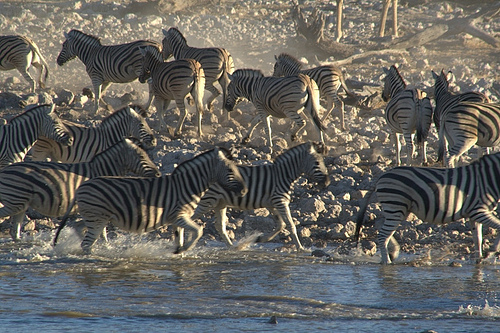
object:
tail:
[352, 185, 375, 243]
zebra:
[353, 152, 500, 262]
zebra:
[225, 68, 326, 148]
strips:
[102, 186, 169, 217]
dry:
[430, 127, 438, 141]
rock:
[301, 196, 328, 212]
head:
[297, 139, 329, 188]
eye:
[312, 161, 320, 165]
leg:
[272, 205, 304, 251]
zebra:
[192, 140, 332, 250]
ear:
[212, 144, 220, 155]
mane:
[171, 149, 214, 175]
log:
[294, 20, 442, 65]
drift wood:
[299, 11, 499, 65]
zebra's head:
[200, 146, 248, 198]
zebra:
[137, 48, 206, 139]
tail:
[192, 73, 204, 112]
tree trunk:
[391, 0, 399, 37]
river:
[0, 245, 499, 331]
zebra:
[77, 137, 250, 272]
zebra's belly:
[396, 186, 462, 224]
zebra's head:
[293, 143, 333, 188]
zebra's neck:
[9, 112, 43, 153]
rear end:
[171, 57, 206, 94]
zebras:
[0, 137, 161, 241]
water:
[0, 248, 499, 333]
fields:
[1, 0, 499, 260]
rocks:
[302, 196, 327, 211]